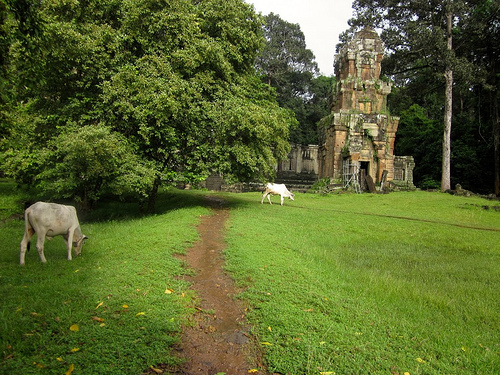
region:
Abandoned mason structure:
[320, 38, 428, 202]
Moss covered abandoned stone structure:
[322, 30, 419, 193]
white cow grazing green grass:
[17, 196, 87, 268]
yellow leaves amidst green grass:
[70, 285, 159, 345]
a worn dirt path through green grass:
[171, 207, 259, 372]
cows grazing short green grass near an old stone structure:
[9, 12, 486, 364]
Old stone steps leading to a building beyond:
[247, 146, 322, 193]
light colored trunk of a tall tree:
[440, 8, 455, 195]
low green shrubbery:
[29, 126, 162, 216]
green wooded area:
[2, 2, 314, 210]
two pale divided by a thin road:
[8, 170, 303, 292]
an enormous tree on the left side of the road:
[1, 0, 308, 225]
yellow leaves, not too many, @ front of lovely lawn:
[2, 262, 498, 373]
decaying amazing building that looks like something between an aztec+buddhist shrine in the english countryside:
[265, 19, 427, 199]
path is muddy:
[149, 192, 273, 372]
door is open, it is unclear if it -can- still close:
[336, 156, 394, 197]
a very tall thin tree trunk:
[435, 0, 459, 198]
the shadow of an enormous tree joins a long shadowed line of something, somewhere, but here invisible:
[4, 184, 498, 261]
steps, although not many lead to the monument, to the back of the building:
[236, 169, 325, 194]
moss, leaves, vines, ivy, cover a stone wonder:
[325, 27, 413, 177]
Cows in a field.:
[5, 55, 312, 322]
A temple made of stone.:
[305, 6, 420, 192]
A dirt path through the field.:
[165, 191, 260, 371]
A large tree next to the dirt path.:
[1, 2, 277, 212]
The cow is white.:
[16, 193, 88, 266]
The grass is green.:
[297, 230, 489, 373]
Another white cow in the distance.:
[257, 180, 295, 205]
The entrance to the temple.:
[355, 157, 373, 189]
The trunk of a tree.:
[436, 2, 453, 192]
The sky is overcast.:
[312, 13, 335, 36]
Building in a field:
[312, 31, 422, 206]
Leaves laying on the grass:
[82, 282, 199, 345]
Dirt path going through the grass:
[180, 240, 265, 371]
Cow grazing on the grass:
[15, 186, 107, 281]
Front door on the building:
[337, 131, 397, 201]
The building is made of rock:
[330, 30, 400, 242]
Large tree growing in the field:
[15, 10, 257, 209]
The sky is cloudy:
[292, 5, 352, 65]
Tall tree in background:
[425, 16, 462, 211]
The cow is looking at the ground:
[258, 166, 305, 213]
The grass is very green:
[262, 213, 484, 360]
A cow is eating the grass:
[13, 195, 93, 270]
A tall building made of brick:
[321, 38, 416, 193]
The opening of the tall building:
[356, 150, 374, 189]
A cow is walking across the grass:
[256, 179, 296, 208]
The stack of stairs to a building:
[246, 169, 315, 196]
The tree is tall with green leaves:
[11, 3, 265, 184]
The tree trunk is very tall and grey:
[437, 2, 458, 201]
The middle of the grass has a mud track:
[183, 196, 253, 371]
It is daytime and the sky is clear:
[265, 3, 352, 74]